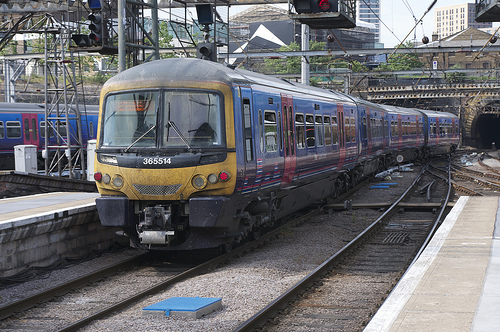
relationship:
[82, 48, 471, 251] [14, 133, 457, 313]
train on tracks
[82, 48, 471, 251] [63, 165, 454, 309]
train on tracks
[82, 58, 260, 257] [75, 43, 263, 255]
engine has front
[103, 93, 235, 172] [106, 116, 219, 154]
windows has wipers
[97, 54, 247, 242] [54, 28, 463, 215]
engine pulling cars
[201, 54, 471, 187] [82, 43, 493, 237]
sides of train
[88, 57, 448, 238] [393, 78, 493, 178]
train came out tunnel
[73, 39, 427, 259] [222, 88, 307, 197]
train with doors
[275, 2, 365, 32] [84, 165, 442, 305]
signal above tracks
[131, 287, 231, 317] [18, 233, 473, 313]
object on tracks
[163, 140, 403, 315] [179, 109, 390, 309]
lines on track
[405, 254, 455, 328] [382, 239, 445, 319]
edge on platform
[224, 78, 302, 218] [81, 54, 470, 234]
door on train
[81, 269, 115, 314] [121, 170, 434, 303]
spot on tracks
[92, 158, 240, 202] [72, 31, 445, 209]
light on train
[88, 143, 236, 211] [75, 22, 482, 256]
light in train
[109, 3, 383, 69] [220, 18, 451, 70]
building in background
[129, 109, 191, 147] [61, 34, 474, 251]
wipers on train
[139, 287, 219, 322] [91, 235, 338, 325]
box on tracks